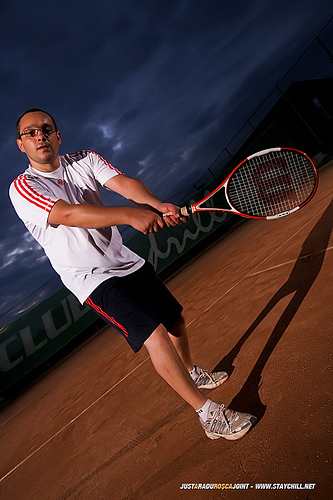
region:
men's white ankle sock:
[190, 398, 214, 420]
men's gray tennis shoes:
[188, 401, 256, 440]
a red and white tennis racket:
[141, 143, 319, 239]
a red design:
[83, 298, 131, 341]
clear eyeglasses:
[18, 127, 61, 135]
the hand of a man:
[129, 210, 166, 235]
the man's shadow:
[209, 198, 332, 421]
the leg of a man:
[84, 283, 214, 421]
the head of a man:
[17, 107, 63, 163]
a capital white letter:
[15, 327, 55, 354]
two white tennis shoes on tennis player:
[166, 358, 256, 436]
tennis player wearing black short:
[88, 264, 188, 340]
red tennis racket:
[146, 143, 320, 238]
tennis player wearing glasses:
[12, 119, 98, 138]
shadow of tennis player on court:
[220, 188, 327, 413]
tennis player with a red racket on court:
[7, 93, 328, 448]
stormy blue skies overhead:
[6, 0, 284, 190]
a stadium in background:
[193, 75, 331, 247]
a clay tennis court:
[4, 342, 330, 498]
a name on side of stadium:
[4, 200, 229, 382]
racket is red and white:
[106, 140, 318, 237]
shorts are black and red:
[89, 266, 189, 351]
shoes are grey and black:
[203, 394, 249, 449]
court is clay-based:
[27, 377, 139, 490]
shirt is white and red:
[19, 133, 121, 299]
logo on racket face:
[247, 158, 292, 219]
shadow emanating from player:
[246, 206, 331, 390]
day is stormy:
[11, 230, 40, 326]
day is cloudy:
[129, 129, 206, 182]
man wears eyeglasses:
[20, 131, 65, 144]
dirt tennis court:
[13, 393, 168, 488]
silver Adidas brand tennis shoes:
[181, 392, 263, 445]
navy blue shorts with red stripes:
[74, 251, 204, 354]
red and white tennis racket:
[151, 137, 327, 243]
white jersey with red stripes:
[2, 141, 159, 303]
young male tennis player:
[1, 100, 330, 443]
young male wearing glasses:
[3, 105, 85, 193]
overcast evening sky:
[50, 8, 242, 96]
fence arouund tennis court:
[238, 13, 331, 93]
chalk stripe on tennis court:
[209, 224, 290, 324]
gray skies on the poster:
[34, 32, 149, 85]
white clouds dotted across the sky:
[90, 118, 187, 157]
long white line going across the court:
[45, 352, 162, 402]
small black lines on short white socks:
[186, 405, 205, 415]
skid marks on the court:
[86, 413, 171, 451]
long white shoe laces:
[211, 400, 240, 435]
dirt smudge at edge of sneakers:
[206, 374, 235, 389]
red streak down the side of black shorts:
[82, 293, 129, 351]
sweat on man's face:
[32, 112, 65, 124]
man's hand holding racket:
[129, 192, 200, 238]